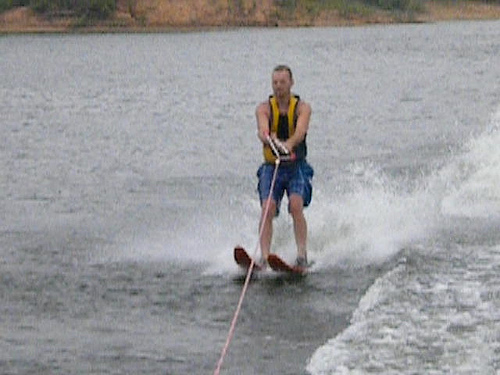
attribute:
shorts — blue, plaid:
[226, 156, 328, 214]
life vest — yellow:
[260, 91, 307, 163]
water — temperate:
[320, 33, 481, 295]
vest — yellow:
[260, 95, 316, 159]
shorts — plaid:
[254, 159, 314, 213]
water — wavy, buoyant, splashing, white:
[3, 25, 498, 372]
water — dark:
[34, 143, 269, 357]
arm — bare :
[285, 102, 315, 152]